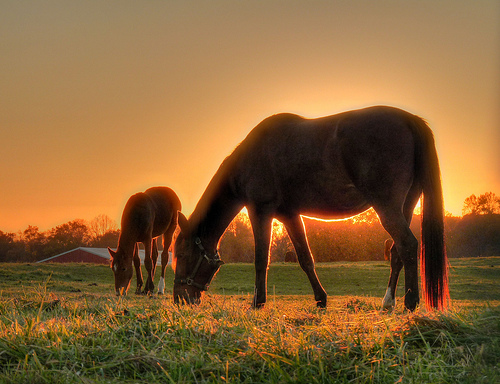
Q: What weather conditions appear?
A: It is cloudy.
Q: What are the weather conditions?
A: It is cloudy.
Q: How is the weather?
A: It is cloudy.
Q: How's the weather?
A: It is cloudy.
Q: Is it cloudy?
A: Yes, it is cloudy.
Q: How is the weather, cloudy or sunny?
A: It is cloudy.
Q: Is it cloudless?
A: No, it is cloudy.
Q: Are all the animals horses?
A: Yes, all the animals are horses.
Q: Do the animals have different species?
A: No, all the animals are horses.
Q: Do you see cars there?
A: No, there are no cars.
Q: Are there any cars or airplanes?
A: No, there are no cars or airplanes.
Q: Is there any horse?
A: Yes, there are horses.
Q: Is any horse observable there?
A: Yes, there are horses.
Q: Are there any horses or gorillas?
A: Yes, there are horses.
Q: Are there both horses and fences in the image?
A: No, there are horses but no fences.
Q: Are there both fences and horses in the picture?
A: No, there are horses but no fences.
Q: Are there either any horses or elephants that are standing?
A: Yes, the horses are standing.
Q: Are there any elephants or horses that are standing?
A: Yes, the horses are standing.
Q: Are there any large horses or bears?
A: Yes, there are large horses.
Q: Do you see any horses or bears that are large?
A: Yes, the horses are large.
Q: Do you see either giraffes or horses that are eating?
A: Yes, the horses are eating.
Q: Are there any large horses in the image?
A: Yes, there are large horses.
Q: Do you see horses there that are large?
A: Yes, there are horses that are large.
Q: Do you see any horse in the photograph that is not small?
A: Yes, there are large horses.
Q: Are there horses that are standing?
A: Yes, there are horses that are standing.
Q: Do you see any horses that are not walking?
A: Yes, there are horses that are standing .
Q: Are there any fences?
A: No, there are no fences.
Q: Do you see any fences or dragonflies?
A: No, there are no fences or dragonflies.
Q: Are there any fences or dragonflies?
A: No, there are no fences or dragonflies.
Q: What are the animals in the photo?
A: The animals are horses.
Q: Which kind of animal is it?
A: The animals are horses.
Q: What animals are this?
A: These are horses.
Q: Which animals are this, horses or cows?
A: These are horses.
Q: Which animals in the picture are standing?
A: The animals are horses.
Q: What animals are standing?
A: The animals are horses.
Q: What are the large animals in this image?
A: The animals are horses.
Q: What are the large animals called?
A: The animals are horses.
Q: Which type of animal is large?
A: The animal is horses.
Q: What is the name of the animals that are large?
A: The animals are horses.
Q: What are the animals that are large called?
A: The animals are horses.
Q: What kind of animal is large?
A: The animal is horses.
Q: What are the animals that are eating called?
A: The animals are horses.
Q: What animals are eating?
A: The animals are horses.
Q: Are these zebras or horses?
A: These are horses.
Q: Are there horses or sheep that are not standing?
A: No, there are horses but they are standing.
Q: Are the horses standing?
A: Yes, the horses are standing.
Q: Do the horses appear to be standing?
A: Yes, the horses are standing.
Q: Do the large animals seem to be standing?
A: Yes, the horses are standing.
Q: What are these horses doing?
A: The horses are standing.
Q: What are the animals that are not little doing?
A: The horses are standing.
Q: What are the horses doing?
A: The horses are standing.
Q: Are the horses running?
A: No, the horses are standing.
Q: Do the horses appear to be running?
A: No, the horses are standing.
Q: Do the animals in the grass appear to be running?
A: No, the horses are standing.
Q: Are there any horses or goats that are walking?
A: No, there are horses but they are standing.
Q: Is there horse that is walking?
A: No, there are horses but they are standing.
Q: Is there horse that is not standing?
A: No, there are horses but they are standing.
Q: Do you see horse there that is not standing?
A: No, there are horses but they are standing.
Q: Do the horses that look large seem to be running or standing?
A: The horses are standing.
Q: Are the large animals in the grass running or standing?
A: The horses are standing.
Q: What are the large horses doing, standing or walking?
A: The horses are standing.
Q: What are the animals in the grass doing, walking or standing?
A: The horses are standing.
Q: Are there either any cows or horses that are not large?
A: No, there are horses but they are large.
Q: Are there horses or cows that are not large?
A: No, there are horses but they are large.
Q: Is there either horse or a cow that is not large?
A: No, there are horses but they are large.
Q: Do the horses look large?
A: Yes, the horses are large.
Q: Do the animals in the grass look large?
A: Yes, the horses are large.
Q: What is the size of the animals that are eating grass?
A: The horses are large.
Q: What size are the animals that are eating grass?
A: The horses are large.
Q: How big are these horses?
A: The horses are large.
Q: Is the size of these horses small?
A: No, the horses are large.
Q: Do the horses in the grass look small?
A: No, the horses are large.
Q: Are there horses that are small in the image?
A: No, there are horses but they are large.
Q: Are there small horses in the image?
A: No, there are horses but they are large.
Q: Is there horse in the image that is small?
A: No, there are horses but they are large.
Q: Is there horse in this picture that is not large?
A: No, there are horses but they are large.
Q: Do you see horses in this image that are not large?
A: No, there are horses but they are large.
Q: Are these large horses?
A: Yes, these are large horses.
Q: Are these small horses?
A: No, these are large horses.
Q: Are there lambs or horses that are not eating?
A: No, there are horses but they are eating.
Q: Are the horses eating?
A: Yes, the horses are eating.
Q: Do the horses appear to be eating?
A: Yes, the horses are eating.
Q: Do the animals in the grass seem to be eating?
A: Yes, the horses are eating.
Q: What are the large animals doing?
A: The horses are eating.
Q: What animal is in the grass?
A: The horses are in the grass.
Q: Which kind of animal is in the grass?
A: The animals are horses.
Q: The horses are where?
A: The horses are in the grass.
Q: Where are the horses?
A: The horses are in the grass.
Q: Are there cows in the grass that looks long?
A: No, there are horses in the grass.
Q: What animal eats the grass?
A: The horses eat the grass.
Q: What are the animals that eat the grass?
A: The animals are horses.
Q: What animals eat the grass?
A: The animals are horses.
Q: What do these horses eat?
A: The horses eat grass.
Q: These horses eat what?
A: The horses eat grass.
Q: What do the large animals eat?
A: The horses eat grass.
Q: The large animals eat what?
A: The horses eat grass.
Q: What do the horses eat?
A: The horses eat grass.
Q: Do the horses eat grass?
A: Yes, the horses eat grass.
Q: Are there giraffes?
A: No, there are no giraffes.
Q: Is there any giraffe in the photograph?
A: No, there are no giraffes.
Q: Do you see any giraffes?
A: No, there are no giraffes.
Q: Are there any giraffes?
A: No, there are no giraffes.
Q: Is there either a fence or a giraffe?
A: No, there are no giraffes or fences.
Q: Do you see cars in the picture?
A: No, there are no cars.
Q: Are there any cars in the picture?
A: No, there are no cars.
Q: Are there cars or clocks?
A: No, there are no cars or clocks.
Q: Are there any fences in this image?
A: No, there are no fences.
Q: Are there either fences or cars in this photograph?
A: No, there are no fences or cars.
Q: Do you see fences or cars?
A: No, there are no fences or cars.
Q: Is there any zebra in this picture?
A: No, there are no zebras.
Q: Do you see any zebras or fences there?
A: No, there are no zebras or fences.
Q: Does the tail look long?
A: Yes, the tail is long.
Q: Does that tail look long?
A: Yes, the tail is long.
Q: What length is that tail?
A: The tail is long.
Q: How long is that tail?
A: The tail is long.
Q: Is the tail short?
A: No, the tail is long.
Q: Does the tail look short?
A: No, the tail is long.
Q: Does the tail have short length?
A: No, the tail is long.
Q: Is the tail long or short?
A: The tail is long.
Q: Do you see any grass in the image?
A: Yes, there is grass.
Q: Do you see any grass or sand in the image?
A: Yes, there is grass.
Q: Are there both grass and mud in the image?
A: No, there is grass but no mud.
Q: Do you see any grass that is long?
A: Yes, there is long grass.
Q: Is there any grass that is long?
A: Yes, there is grass that is long.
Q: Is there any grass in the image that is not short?
A: Yes, there is long grass.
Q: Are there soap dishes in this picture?
A: No, there are no soap dishes.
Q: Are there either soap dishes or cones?
A: No, there are no soap dishes or cones.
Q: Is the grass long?
A: Yes, the grass is long.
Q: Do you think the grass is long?
A: Yes, the grass is long.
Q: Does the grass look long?
A: Yes, the grass is long.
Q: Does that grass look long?
A: Yes, the grass is long.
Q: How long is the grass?
A: The grass is long.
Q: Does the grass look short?
A: No, the grass is long.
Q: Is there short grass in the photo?
A: No, there is grass but it is long.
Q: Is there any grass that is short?
A: No, there is grass but it is long.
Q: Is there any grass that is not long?
A: No, there is grass but it is long.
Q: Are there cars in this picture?
A: No, there are no cars.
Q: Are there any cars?
A: No, there are no cars.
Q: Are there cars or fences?
A: No, there are no cars or fences.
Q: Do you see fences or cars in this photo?
A: No, there are no cars or fences.